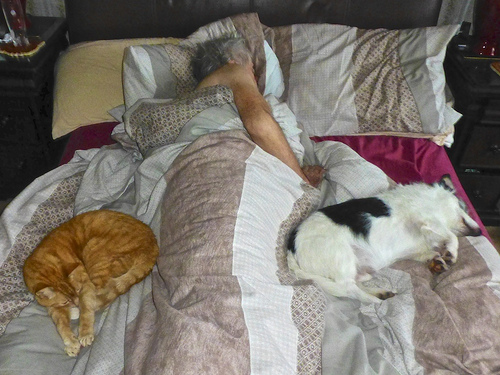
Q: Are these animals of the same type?
A: No, they are dogs and cats.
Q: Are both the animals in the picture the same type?
A: No, they are dogs and cats.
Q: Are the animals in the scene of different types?
A: Yes, they are dogs and cats.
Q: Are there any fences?
A: No, there are no fences.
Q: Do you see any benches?
A: No, there are no benches.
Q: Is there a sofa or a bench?
A: No, there are no benches or sofas.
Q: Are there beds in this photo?
A: Yes, there is a bed.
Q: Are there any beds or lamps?
A: Yes, there is a bed.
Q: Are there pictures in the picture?
A: No, there are no pictures.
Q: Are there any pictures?
A: No, there are no pictures.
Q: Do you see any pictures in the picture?
A: No, there are no pictures.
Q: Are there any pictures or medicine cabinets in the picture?
A: No, there are no pictures or medicine cabinets.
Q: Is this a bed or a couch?
A: This is a bed.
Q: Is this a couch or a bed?
A: This is a bed.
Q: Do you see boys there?
A: No, there are no boys.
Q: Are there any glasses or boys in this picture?
A: No, there are no boys or glasses.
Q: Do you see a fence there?
A: No, there are no fences.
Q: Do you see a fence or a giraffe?
A: No, there are no fences or giraffes.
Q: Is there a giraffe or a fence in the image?
A: No, there are no fences or giraffes.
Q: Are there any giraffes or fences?
A: No, there are no fences or giraffes.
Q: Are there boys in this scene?
A: No, there are no boys.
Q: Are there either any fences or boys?
A: No, there are no boys or fences.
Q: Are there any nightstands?
A: Yes, there is a nightstand.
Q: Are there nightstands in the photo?
A: Yes, there is a nightstand.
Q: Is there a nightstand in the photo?
A: Yes, there is a nightstand.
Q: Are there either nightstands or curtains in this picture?
A: Yes, there is a nightstand.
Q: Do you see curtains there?
A: No, there are no curtains.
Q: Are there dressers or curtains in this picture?
A: No, there are no curtains or dressers.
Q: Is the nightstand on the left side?
A: Yes, the nightstand is on the left of the image.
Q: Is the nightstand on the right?
A: No, the nightstand is on the left of the image.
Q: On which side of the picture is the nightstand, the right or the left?
A: The nightstand is on the left of the image.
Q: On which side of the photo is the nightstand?
A: The nightstand is on the left of the image.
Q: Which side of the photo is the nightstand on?
A: The nightstand is on the left of the image.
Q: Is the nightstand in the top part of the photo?
A: Yes, the nightstand is in the top of the image.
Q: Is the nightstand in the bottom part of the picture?
A: No, the nightstand is in the top of the image.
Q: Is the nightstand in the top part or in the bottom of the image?
A: The nightstand is in the top of the image.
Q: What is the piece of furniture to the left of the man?
A: The piece of furniture is a nightstand.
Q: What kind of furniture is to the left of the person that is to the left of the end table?
A: The piece of furniture is a nightstand.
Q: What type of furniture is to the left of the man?
A: The piece of furniture is a nightstand.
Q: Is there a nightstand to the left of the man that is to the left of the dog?
A: Yes, there is a nightstand to the left of the man.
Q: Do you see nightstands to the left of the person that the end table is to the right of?
A: Yes, there is a nightstand to the left of the man.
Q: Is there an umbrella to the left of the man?
A: No, there is a nightstand to the left of the man.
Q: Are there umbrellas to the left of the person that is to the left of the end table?
A: No, there is a nightstand to the left of the man.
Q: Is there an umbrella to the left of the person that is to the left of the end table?
A: No, there is a nightstand to the left of the man.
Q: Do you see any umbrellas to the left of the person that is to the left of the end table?
A: No, there is a nightstand to the left of the man.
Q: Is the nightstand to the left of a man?
A: Yes, the nightstand is to the left of a man.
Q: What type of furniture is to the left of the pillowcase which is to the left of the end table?
A: The piece of furniture is a nightstand.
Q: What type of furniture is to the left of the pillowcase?
A: The piece of furniture is a nightstand.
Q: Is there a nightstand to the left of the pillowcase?
A: Yes, there is a nightstand to the left of the pillowcase.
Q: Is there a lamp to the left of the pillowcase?
A: No, there is a nightstand to the left of the pillowcase.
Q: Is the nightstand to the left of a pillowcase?
A: Yes, the nightstand is to the left of a pillowcase.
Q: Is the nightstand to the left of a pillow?
A: No, the nightstand is to the left of a pillowcase.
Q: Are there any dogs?
A: Yes, there is a dog.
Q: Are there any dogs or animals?
A: Yes, there is a dog.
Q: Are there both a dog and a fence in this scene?
A: No, there is a dog but no fences.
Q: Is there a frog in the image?
A: No, there are no frogs.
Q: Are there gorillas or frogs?
A: No, there are no frogs or gorillas.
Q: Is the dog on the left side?
A: No, the dog is on the right of the image.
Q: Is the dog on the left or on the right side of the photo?
A: The dog is on the right of the image.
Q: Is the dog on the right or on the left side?
A: The dog is on the right of the image.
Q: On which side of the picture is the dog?
A: The dog is on the right of the image.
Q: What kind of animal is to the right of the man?
A: The animal is a dog.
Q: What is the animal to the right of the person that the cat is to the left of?
A: The animal is a dog.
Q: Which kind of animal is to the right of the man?
A: The animal is a dog.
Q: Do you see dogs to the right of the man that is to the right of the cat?
A: Yes, there is a dog to the right of the man.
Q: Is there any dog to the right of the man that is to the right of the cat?
A: Yes, there is a dog to the right of the man.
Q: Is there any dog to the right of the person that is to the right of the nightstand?
A: Yes, there is a dog to the right of the man.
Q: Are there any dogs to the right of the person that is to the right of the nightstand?
A: Yes, there is a dog to the right of the man.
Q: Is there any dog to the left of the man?
A: No, the dog is to the right of the man.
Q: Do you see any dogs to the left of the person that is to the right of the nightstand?
A: No, the dog is to the right of the man.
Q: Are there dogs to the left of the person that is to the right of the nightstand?
A: No, the dog is to the right of the man.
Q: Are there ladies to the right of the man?
A: No, there is a dog to the right of the man.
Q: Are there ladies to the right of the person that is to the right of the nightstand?
A: No, there is a dog to the right of the man.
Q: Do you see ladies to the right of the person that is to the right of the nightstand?
A: No, there is a dog to the right of the man.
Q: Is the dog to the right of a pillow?
A: No, the dog is to the right of the man.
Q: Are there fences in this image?
A: No, there are no fences.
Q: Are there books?
A: No, there are no books.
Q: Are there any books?
A: No, there are no books.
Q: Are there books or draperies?
A: No, there are no books or draperies.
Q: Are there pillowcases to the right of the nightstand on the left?
A: Yes, there is a pillowcase to the right of the nightstand.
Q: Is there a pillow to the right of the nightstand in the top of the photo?
A: No, there is a pillowcase to the right of the nightstand.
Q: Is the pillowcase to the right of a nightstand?
A: Yes, the pillowcase is to the right of a nightstand.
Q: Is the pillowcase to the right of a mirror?
A: No, the pillowcase is to the right of a nightstand.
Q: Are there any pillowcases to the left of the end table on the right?
A: Yes, there is a pillowcase to the left of the end table.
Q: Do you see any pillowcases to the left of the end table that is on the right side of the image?
A: Yes, there is a pillowcase to the left of the end table.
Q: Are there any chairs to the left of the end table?
A: No, there is a pillowcase to the left of the end table.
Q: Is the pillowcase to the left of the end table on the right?
A: Yes, the pillowcase is to the left of the end table.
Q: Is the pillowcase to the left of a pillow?
A: No, the pillowcase is to the left of the end table.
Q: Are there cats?
A: Yes, there is a cat.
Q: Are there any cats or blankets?
A: Yes, there is a cat.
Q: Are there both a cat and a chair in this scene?
A: No, there is a cat but no chairs.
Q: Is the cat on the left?
A: Yes, the cat is on the left of the image.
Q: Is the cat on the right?
A: No, the cat is on the left of the image.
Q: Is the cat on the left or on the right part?
A: The cat is on the left of the image.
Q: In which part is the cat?
A: The cat is on the left of the image.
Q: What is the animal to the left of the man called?
A: The animal is a cat.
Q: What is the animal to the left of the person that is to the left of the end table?
A: The animal is a cat.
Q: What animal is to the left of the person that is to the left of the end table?
A: The animal is a cat.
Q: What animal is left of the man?
A: The animal is a cat.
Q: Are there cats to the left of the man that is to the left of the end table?
A: Yes, there is a cat to the left of the man.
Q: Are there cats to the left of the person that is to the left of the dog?
A: Yes, there is a cat to the left of the man.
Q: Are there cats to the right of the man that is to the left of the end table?
A: No, the cat is to the left of the man.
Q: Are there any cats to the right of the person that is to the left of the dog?
A: No, the cat is to the left of the man.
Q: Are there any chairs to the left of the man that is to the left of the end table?
A: No, there is a cat to the left of the man.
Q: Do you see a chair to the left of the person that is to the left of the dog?
A: No, there is a cat to the left of the man.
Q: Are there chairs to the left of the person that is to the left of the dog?
A: No, there is a cat to the left of the man.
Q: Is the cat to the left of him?
A: Yes, the cat is to the left of a man.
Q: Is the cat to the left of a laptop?
A: No, the cat is to the left of a man.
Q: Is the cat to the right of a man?
A: No, the cat is to the left of a man.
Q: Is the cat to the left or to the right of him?
A: The cat is to the left of the man.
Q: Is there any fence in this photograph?
A: No, there are no fences.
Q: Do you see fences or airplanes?
A: No, there are no fences or airplanes.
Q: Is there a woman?
A: No, there are no women.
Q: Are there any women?
A: No, there are no women.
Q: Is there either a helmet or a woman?
A: No, there are no women or helmets.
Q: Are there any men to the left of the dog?
A: Yes, there is a man to the left of the dog.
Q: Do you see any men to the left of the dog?
A: Yes, there is a man to the left of the dog.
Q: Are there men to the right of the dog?
A: No, the man is to the left of the dog.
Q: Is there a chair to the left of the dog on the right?
A: No, there is a man to the left of the dog.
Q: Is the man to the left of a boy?
A: No, the man is to the left of the dog.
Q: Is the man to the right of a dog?
A: No, the man is to the left of a dog.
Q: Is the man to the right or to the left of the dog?
A: The man is to the left of the dog.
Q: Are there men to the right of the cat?
A: Yes, there is a man to the right of the cat.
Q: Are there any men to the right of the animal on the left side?
A: Yes, there is a man to the right of the cat.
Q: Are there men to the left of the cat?
A: No, the man is to the right of the cat.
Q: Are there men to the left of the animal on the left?
A: No, the man is to the right of the cat.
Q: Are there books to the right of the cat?
A: No, there is a man to the right of the cat.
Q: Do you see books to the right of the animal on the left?
A: No, there is a man to the right of the cat.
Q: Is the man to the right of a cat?
A: Yes, the man is to the right of a cat.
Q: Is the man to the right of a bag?
A: No, the man is to the right of a cat.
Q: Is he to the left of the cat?
A: No, the man is to the right of the cat.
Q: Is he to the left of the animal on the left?
A: No, the man is to the right of the cat.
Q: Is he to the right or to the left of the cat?
A: The man is to the right of the cat.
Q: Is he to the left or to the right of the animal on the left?
A: The man is to the right of the cat.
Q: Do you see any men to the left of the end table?
A: Yes, there is a man to the left of the end table.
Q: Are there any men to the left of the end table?
A: Yes, there is a man to the left of the end table.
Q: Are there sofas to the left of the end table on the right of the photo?
A: No, there is a man to the left of the end table.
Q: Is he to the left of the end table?
A: Yes, the man is to the left of the end table.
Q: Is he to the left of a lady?
A: No, the man is to the left of the end table.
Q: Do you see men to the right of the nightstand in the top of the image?
A: Yes, there is a man to the right of the nightstand.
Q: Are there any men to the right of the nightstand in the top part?
A: Yes, there is a man to the right of the nightstand.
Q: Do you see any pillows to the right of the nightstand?
A: No, there is a man to the right of the nightstand.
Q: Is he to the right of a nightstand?
A: Yes, the man is to the right of a nightstand.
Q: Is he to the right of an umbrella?
A: No, the man is to the right of a nightstand.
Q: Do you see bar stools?
A: No, there are no bar stools.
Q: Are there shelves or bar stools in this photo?
A: No, there are no bar stools or shelves.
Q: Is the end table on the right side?
A: Yes, the end table is on the right of the image.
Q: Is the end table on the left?
A: No, the end table is on the right of the image.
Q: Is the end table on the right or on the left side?
A: The end table is on the right of the image.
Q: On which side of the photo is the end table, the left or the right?
A: The end table is on the right of the image.